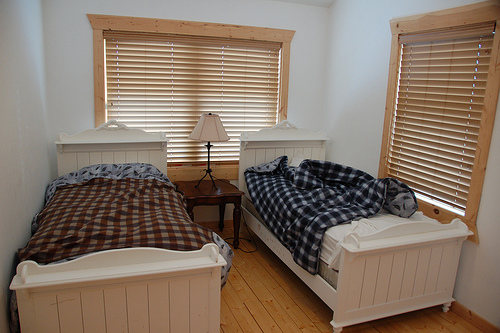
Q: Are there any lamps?
A: Yes, there is a lamp.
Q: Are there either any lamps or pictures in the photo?
A: Yes, there is a lamp.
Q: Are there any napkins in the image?
A: No, there are no napkins.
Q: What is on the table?
A: The lamp is on the table.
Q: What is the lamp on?
A: The lamp is on the table.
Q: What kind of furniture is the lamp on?
A: The lamp is on the table.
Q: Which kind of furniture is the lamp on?
A: The lamp is on the table.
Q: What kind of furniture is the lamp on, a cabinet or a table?
A: The lamp is on a table.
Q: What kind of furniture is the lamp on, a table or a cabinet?
A: The lamp is on a table.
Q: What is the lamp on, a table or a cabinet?
A: The lamp is on a table.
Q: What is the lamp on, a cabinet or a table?
A: The lamp is on a table.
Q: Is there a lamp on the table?
A: Yes, there is a lamp on the table.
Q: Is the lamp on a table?
A: Yes, the lamp is on a table.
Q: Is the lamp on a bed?
A: No, the lamp is on a table.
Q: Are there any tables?
A: Yes, there is a table.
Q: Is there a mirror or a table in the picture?
A: Yes, there is a table.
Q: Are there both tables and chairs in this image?
A: No, there is a table but no chairs.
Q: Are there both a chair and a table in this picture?
A: No, there is a table but no chairs.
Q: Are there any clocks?
A: No, there are no clocks.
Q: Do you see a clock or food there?
A: No, there are no clocks or food.